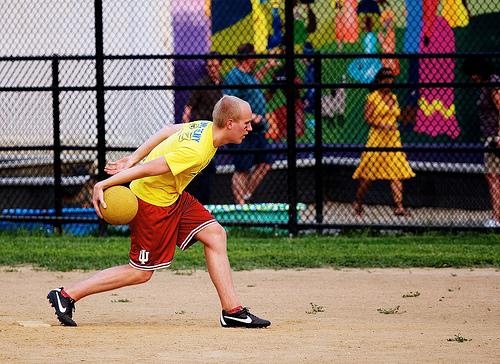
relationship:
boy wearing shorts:
[45, 94, 275, 329] [122, 181, 212, 262]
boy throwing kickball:
[45, 94, 275, 329] [95, 185, 138, 225]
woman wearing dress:
[345, 60, 421, 217] [348, 91, 420, 182]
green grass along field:
[1, 227, 499, 273] [15, 221, 498, 356]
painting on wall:
[211, 7, 466, 134] [11, 2, 498, 186]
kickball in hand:
[98, 185, 138, 224] [90, 184, 105, 218]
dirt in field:
[310, 283, 382, 345] [3, 231, 494, 359]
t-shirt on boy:
[128, 121, 218, 206] [40, 91, 274, 332]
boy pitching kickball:
[40, 91, 274, 332] [95, 185, 138, 225]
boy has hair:
[40, 91, 274, 332] [208, 91, 242, 121]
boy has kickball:
[40, 91, 274, 332] [68, 155, 164, 272]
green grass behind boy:
[1, 227, 499, 271] [40, 91, 274, 332]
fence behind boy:
[244, 20, 498, 240] [46, 70, 273, 342]